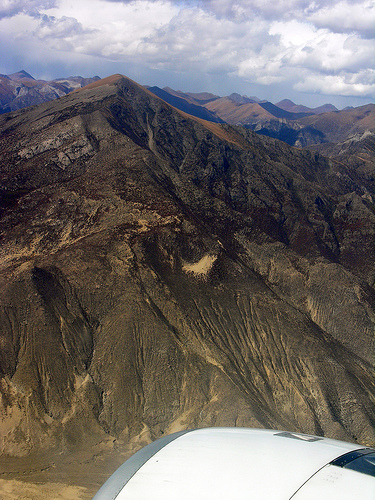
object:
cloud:
[0, 0, 375, 93]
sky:
[0, 0, 375, 91]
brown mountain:
[0, 239, 375, 499]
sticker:
[271, 427, 327, 446]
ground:
[306, 97, 375, 212]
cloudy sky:
[0, 3, 375, 88]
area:
[178, 248, 219, 275]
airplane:
[88, 424, 374, 499]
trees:
[130, 135, 280, 239]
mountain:
[0, 64, 375, 500]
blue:
[163, 71, 198, 89]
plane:
[98, 425, 375, 500]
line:
[219, 342, 375, 445]